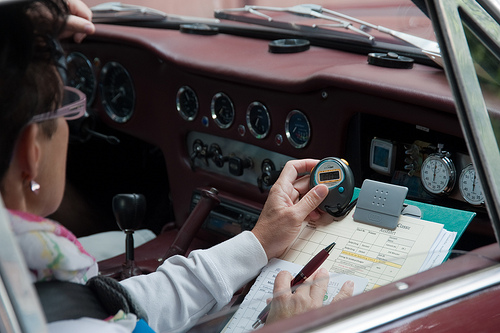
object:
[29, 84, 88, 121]
glasses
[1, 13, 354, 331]
woman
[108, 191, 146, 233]
rubber ball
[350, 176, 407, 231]
clip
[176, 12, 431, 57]
wipers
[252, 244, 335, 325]
pen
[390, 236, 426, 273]
paper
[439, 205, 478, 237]
board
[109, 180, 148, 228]
top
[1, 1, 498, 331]
scene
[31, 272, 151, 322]
seat belt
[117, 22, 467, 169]
dashboard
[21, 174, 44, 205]
earring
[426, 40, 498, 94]
crome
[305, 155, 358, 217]
stopwatch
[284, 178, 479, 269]
clipboard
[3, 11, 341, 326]
lady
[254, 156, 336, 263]
hand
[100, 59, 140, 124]
pedometer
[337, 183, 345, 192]
button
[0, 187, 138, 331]
seat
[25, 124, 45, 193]
ear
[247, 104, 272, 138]
gauge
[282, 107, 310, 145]
gauge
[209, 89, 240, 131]
gauge